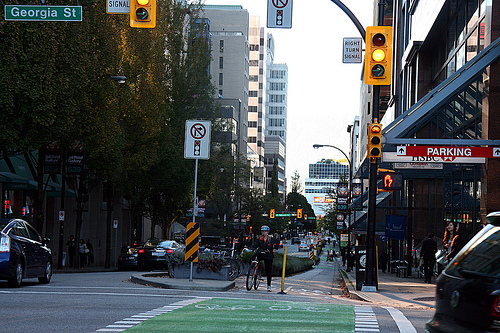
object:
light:
[361, 42, 397, 70]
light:
[369, 124, 385, 135]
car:
[0, 214, 61, 289]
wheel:
[34, 256, 56, 285]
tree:
[75, 0, 158, 265]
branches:
[61, 48, 102, 101]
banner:
[392, 143, 500, 159]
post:
[362, 166, 383, 291]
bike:
[240, 245, 271, 293]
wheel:
[244, 261, 259, 292]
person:
[249, 222, 286, 292]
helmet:
[259, 224, 271, 232]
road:
[1, 297, 427, 333]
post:
[278, 243, 291, 293]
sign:
[0, 3, 88, 25]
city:
[2, 0, 500, 332]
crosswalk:
[89, 272, 415, 333]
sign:
[392, 144, 500, 160]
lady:
[435, 215, 466, 268]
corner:
[367, 278, 437, 311]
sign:
[181, 118, 214, 162]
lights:
[0, 235, 13, 255]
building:
[198, 0, 297, 252]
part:
[372, 56, 387, 61]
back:
[424, 207, 499, 331]